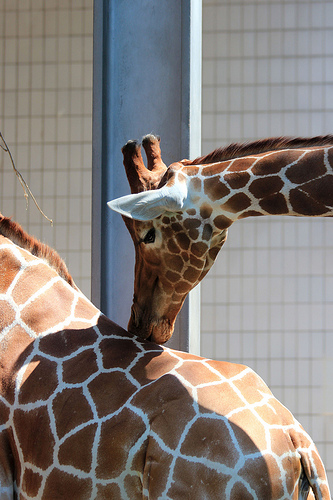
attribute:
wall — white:
[204, 217, 332, 354]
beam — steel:
[90, 0, 203, 357]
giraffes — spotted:
[12, 39, 325, 499]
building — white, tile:
[195, 1, 332, 442]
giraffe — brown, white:
[90, 132, 288, 306]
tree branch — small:
[0, 131, 51, 225]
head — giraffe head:
[102, 118, 232, 338]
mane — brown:
[182, 133, 332, 165]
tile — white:
[223, 270, 305, 350]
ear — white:
[106, 173, 190, 221]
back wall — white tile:
[14, 45, 72, 177]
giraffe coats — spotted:
[0, 151, 329, 494]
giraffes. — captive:
[1, 127, 330, 496]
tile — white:
[244, 251, 312, 372]